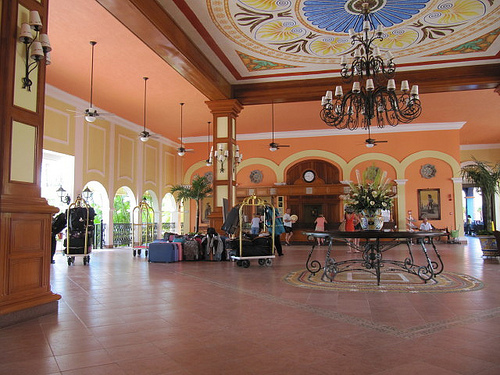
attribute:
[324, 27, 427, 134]
chandelier — large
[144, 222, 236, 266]
pile — luggage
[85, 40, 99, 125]
pendant light — black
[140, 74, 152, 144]
pendant light — black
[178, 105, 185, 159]
pendant light — black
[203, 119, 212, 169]
pendant light — black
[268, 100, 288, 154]
pendant light — black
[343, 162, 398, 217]
plant — large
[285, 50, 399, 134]
light — pendant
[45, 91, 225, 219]
walls — yellow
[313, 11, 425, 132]
chandelier — black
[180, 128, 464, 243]
wall — peach 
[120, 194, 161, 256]
wheeled cart — empty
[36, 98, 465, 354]
lobby — hotel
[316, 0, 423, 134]
chandelier — hanging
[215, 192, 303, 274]
cart — wheeled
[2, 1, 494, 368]
lobby — fancy, hotel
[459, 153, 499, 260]
floor plant — large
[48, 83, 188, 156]
molding — white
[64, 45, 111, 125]
light — pendant